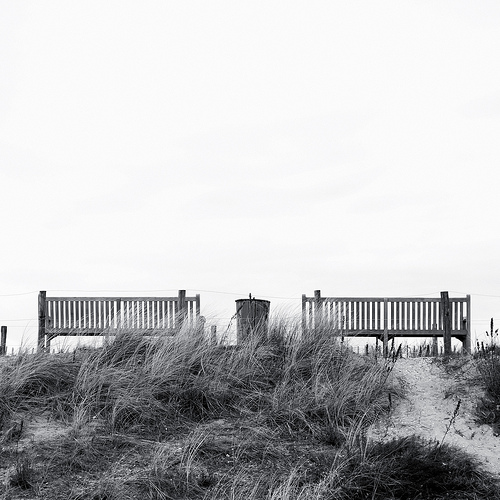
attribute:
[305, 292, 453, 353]
posts — wooden, for security, at entrance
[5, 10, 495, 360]
sky — clear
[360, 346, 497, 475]
sand — beach's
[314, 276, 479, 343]
bench — at right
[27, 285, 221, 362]
bench — wood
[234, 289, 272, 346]
trash can — trash's, in midle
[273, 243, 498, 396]
bench — park's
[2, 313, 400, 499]
grass — tall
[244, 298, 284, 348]
trash can — trash's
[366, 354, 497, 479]
path — sand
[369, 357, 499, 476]
sand — path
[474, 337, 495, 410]
bush — wild ,  sticker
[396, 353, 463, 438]
patch area — dirt